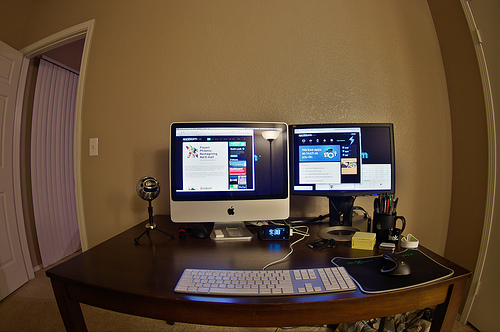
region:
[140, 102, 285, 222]
grey screen on desk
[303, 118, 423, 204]
black second monitor for desktop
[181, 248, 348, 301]
white keys on keyboard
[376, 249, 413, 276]
black mouse on mousepad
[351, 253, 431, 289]
mousepad on black desk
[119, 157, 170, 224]
webcam next to monitor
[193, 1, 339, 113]
tan wall behind monitors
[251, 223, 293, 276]
white cable for keyboard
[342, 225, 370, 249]
stack of yellow notes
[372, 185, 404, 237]
black mug with pens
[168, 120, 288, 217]
an apple monitor with screen turned on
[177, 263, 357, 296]
white computer keyboard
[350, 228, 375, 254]
a stack of yellow sticky notes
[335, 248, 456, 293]
black and green mouse pad with white trim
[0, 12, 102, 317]
doorway with open white door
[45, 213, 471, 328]
dark brown wooden desk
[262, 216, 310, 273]
long white cord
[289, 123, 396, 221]
black computer monitor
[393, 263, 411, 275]
dark gray computer mouse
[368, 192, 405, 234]
black coffee cup full of pens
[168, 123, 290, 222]
a white computer monitor on a desk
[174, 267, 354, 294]
a slim white keyboard on a desk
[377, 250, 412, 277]
a black and gray computer mouse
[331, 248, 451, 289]
a black mouse pad with white borders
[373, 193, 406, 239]
various pens in a black mug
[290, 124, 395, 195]
a black monitor on a desk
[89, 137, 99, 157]
a light switch on the wall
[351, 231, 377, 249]
a stack of yellow post-it notes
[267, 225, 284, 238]
a blue light on a charger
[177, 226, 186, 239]
a black and red usb key on a desk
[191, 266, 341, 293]
the keyboard is white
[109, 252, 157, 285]
the desk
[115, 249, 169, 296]
the desk is brown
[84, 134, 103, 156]
a light switch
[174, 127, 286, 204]
a computer monitor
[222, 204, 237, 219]
logo of the brand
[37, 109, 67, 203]
the blinds are white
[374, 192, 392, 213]
a cup of pens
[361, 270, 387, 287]
a mouse pad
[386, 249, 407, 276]
the mouse